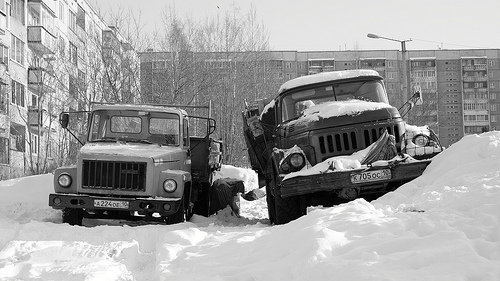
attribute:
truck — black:
[67, 97, 198, 213]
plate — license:
[82, 184, 144, 209]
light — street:
[375, 28, 419, 140]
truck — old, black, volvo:
[232, 43, 454, 213]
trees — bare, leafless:
[1, 0, 316, 178]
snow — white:
[345, 189, 480, 256]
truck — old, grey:
[42, 100, 253, 232]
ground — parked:
[346, 132, 398, 182]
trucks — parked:
[39, 63, 454, 231]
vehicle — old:
[235, 66, 458, 225]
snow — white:
[10, 220, 499, 277]